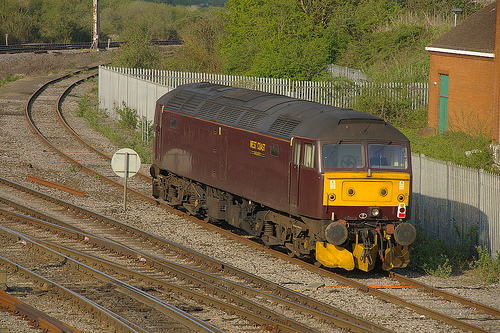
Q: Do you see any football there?
A: No, there are no footballs.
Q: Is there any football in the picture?
A: No, there are no footballs.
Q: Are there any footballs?
A: No, there are no footballs.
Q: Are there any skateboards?
A: No, there are no skateboards.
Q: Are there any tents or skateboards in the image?
A: No, there are no skateboards or tents.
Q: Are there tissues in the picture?
A: No, there are no tissues.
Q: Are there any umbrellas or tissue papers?
A: No, there are no tissue papers or umbrellas.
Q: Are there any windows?
A: Yes, there are windows.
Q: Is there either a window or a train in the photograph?
A: Yes, there are windows.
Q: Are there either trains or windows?
A: Yes, there are windows.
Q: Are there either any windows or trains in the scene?
A: Yes, there are windows.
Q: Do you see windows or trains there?
A: Yes, there are windows.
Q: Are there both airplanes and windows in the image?
A: No, there are windows but no airplanes.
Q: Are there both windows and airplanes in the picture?
A: No, there are windows but no airplanes.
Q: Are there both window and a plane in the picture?
A: No, there are windows but no airplanes.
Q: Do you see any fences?
A: Yes, there is a fence.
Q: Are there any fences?
A: Yes, there is a fence.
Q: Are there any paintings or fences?
A: Yes, there is a fence.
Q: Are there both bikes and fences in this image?
A: No, there is a fence but no bikes.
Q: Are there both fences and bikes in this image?
A: No, there is a fence but no bikes.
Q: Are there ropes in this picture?
A: No, there are no ropes.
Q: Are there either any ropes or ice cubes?
A: No, there are no ropes or ice cubes.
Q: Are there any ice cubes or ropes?
A: No, there are no ropes or ice cubes.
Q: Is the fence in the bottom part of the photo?
A: No, the fence is in the top of the image.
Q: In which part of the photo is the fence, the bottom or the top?
A: The fence is in the top of the image.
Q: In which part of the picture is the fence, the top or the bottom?
A: The fence is in the top of the image.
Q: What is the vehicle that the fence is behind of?
A: The vehicle is a train.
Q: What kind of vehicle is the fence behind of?
A: The fence is behind the train.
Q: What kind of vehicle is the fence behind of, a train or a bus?
A: The fence is behind a train.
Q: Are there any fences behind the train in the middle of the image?
A: Yes, there is a fence behind the train.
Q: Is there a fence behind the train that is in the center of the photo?
A: Yes, there is a fence behind the train.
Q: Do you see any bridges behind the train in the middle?
A: No, there is a fence behind the train.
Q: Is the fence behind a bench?
A: No, the fence is behind the train.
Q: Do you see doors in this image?
A: Yes, there is a door.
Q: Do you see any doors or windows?
A: Yes, there is a door.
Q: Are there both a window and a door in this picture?
A: Yes, there are both a door and a window.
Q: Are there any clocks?
A: No, there are no clocks.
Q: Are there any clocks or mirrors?
A: No, there are no clocks or mirrors.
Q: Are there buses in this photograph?
A: No, there are no buses.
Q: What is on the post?
A: The sign is on the post.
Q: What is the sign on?
A: The sign is on the post.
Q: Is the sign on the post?
A: Yes, the sign is on the post.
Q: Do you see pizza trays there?
A: No, there are no pizza trays.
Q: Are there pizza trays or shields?
A: No, there are no pizza trays or shields.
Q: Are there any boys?
A: No, there are no boys.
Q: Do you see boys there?
A: No, there are no boys.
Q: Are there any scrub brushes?
A: No, there are no scrub brushes.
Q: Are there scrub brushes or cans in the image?
A: No, there are no scrub brushes or cans.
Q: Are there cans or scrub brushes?
A: No, there are no scrub brushes or cans.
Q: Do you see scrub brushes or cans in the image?
A: No, there are no scrub brushes or cans.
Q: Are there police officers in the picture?
A: No, there are no police officers.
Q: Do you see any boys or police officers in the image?
A: No, there are no police officers or boys.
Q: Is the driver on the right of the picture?
A: Yes, the driver is on the right of the image.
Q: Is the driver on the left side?
A: No, the driver is on the right of the image.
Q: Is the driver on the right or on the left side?
A: The driver is on the right of the image.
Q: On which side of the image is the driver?
A: The driver is on the right of the image.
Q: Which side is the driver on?
A: The driver is on the right of the image.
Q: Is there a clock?
A: No, there are no clocks.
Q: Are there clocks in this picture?
A: No, there are no clocks.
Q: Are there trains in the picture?
A: Yes, there is a train.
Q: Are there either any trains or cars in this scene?
A: Yes, there is a train.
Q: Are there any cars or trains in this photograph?
A: Yes, there is a train.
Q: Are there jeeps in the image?
A: No, there are no jeeps.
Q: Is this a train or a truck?
A: This is a train.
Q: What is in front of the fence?
A: The train is in front of the fence.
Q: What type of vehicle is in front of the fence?
A: The vehicle is a train.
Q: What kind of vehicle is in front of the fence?
A: The vehicle is a train.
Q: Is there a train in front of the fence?
A: Yes, there is a train in front of the fence.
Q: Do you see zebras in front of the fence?
A: No, there is a train in front of the fence.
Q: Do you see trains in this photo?
A: Yes, there is a train.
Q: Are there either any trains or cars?
A: Yes, there is a train.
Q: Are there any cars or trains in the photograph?
A: Yes, there is a train.